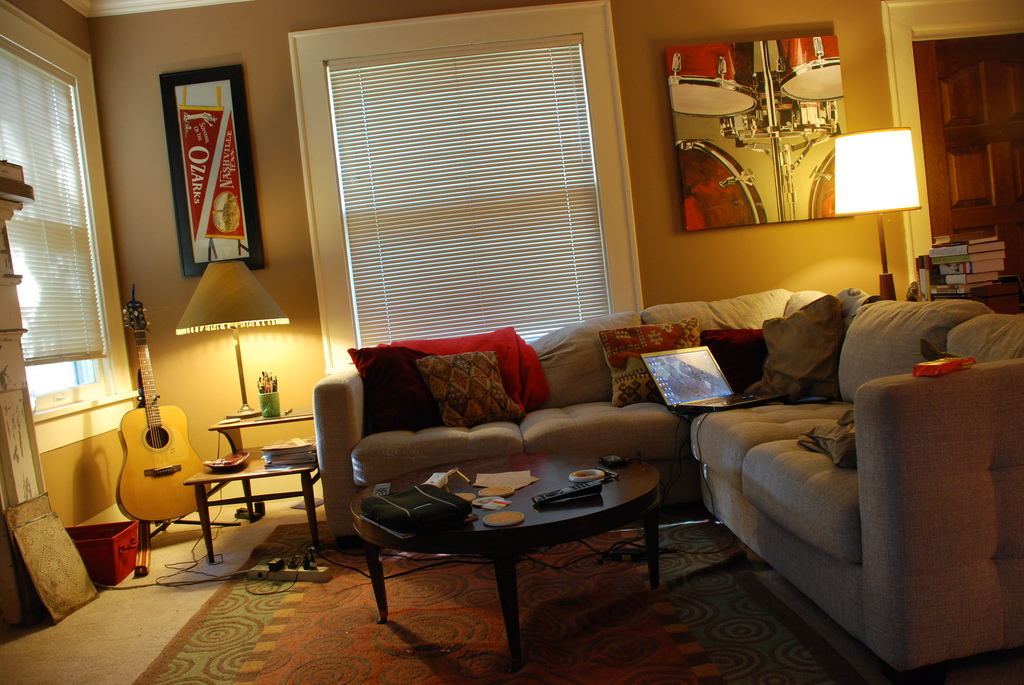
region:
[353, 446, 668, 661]
Round wooden coffee table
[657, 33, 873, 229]
Picture of a drum set hanging on the wall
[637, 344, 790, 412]
Laptop with it's screen turned on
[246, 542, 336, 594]
Power strip with three black plugs connected to it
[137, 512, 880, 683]
Multicolored area rug with a swirl pattern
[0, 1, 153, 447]
Window with it's shade almost completely down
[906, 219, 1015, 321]
Stack of books on a table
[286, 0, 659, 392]
Window with white blinds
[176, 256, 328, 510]
Lit electric lamp on a small table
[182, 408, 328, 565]
wooden side table next to couch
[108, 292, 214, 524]
acoustic guitar in corner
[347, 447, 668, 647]
round wooden coffee table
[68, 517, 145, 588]
red storage bin with handle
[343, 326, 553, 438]
colorful decorative pillows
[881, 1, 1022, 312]
white trimmed wood front door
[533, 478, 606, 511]
remote control for TV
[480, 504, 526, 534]
round cork drink coaster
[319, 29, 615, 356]
white closed miniblinds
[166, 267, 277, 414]
a lamp on a small table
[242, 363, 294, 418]
a small green vase on a table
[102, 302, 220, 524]
a guitar that is brown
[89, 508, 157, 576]
a small red storage box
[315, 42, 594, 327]
a window that is really big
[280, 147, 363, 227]
the border of a window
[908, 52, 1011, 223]
a door that is brown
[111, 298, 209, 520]
a guitar sitting on a stand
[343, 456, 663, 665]
a round wooden coffee table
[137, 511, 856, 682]
a red, green and brown carpet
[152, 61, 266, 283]
a black framed picture on the wall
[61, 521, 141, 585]
a red hard plastic container on the floor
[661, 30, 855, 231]
a square painting hanging on the wall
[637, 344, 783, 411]
an open laptop sitting on the couch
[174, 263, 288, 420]
a lamp on top of a small table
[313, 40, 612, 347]
white blinds on the window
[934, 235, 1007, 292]
a stack of books on a table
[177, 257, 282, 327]
the lamp is on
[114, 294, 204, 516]
guitar in the corner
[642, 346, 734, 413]
table on the sofa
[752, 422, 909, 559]
A cushion on a couch.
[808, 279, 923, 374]
A cushion on a couch.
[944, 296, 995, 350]
A cushion on a couch.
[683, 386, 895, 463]
A cushion on a couch.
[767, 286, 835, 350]
A cushion on a couch.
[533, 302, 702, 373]
A cushion on a couch.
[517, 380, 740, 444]
A cushion on a couch.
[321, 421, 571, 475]
A cushion on a couch.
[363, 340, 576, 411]
A cushion on a couch.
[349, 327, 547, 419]
red throw blanket on beige sofa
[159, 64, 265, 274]
art in black frame hangs on wall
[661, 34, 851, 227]
drums canvas art hangs on wall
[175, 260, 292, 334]
beige fringed shade on table lamp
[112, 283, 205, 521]
acoustic guitar on stand in the corner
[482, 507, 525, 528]
round white coaster on table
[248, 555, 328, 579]
black cords plugged into white surge protector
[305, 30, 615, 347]
white blinds on large white trimmed window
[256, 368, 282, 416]
green cup of writing utensils on wooden side table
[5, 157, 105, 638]
side of fireplace unit in home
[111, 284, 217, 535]
guitar stood in corner of room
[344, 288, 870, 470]
whole bunch of decorative pillows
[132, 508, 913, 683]
multi-colored area rug covering floor